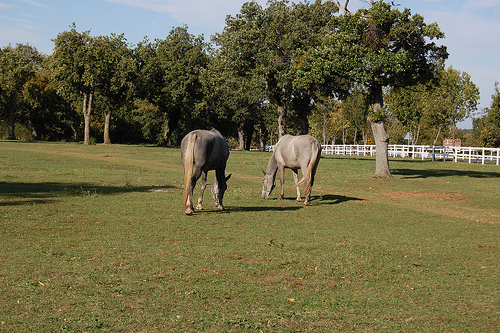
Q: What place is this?
A: It is a field.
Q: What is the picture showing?
A: It is showing a field.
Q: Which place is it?
A: It is a field.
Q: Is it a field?
A: Yes, it is a field.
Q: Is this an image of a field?
A: Yes, it is showing a field.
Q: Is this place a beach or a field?
A: It is a field.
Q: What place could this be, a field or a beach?
A: It is a field.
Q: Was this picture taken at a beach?
A: No, the picture was taken in a field.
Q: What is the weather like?
A: It is cloudy.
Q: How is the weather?
A: It is cloudy.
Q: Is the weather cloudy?
A: Yes, it is cloudy.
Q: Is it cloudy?
A: Yes, it is cloudy.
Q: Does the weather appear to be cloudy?
A: Yes, it is cloudy.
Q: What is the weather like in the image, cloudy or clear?
A: It is cloudy.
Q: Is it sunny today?
A: No, it is cloudy.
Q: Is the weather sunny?
A: No, it is cloudy.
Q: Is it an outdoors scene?
A: Yes, it is outdoors.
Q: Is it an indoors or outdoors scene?
A: It is outdoors.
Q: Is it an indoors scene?
A: No, it is outdoors.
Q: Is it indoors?
A: No, it is outdoors.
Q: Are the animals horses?
A: Yes, all the animals are horses.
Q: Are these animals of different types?
A: No, all the animals are horses.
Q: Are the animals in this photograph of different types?
A: No, all the animals are horses.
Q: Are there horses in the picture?
A: Yes, there is a horse.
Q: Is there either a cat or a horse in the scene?
A: Yes, there is a horse.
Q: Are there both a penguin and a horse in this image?
A: No, there is a horse but no penguins.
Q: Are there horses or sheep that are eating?
A: Yes, the horse is eating.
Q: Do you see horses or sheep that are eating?
A: Yes, the horse is eating.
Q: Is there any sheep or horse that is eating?
A: Yes, the horse is eating.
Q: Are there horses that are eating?
A: Yes, there is a horse that is eating.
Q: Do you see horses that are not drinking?
A: Yes, there is a horse that is eating .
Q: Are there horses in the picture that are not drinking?
A: Yes, there is a horse that is eating.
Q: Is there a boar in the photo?
A: No, there are no boars.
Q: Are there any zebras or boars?
A: No, there are no boars or zebras.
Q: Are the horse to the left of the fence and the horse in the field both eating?
A: Yes, both the horse and the horse are eating.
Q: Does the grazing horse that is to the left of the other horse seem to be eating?
A: Yes, the horse is eating.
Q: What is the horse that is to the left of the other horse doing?
A: The horse is eating.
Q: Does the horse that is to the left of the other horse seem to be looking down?
A: No, the horse is eating.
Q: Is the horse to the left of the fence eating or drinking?
A: The horse is eating.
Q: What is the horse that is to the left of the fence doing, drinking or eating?
A: The horse is eating.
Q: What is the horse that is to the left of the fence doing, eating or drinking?
A: The horse is eating.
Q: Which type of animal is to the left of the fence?
A: The animal is a horse.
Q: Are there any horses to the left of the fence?
A: Yes, there is a horse to the left of the fence.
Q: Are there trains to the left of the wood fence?
A: No, there is a horse to the left of the fence.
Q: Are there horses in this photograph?
A: Yes, there is a horse.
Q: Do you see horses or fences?
A: Yes, there is a horse.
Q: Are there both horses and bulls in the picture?
A: No, there is a horse but no bulls.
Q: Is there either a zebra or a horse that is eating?
A: Yes, the horse is eating.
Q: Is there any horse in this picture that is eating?
A: Yes, there is a horse that is eating.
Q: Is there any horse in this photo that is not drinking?
A: Yes, there is a horse that is eating.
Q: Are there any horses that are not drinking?
A: Yes, there is a horse that is eating.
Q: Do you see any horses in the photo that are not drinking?
A: Yes, there is a horse that is eating .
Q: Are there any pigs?
A: No, there are no pigs.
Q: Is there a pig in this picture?
A: No, there are no pigs.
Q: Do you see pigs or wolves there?
A: No, there are no pigs or wolves.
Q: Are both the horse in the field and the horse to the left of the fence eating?
A: Yes, both the horse and the horse are eating.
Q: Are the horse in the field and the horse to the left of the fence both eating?
A: Yes, both the horse and the horse are eating.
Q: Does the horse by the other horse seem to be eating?
A: Yes, the horse is eating.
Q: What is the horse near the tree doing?
A: The horse is eating.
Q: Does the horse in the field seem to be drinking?
A: No, the horse is eating.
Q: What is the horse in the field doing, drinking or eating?
A: The horse is eating.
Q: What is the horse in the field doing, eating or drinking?
A: The horse is eating.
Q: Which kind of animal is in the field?
A: The animal is a horse.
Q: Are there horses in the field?
A: Yes, there is a horse in the field.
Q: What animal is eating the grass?
A: The horse is eating the grass.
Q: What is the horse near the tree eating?
A: The horse is eating grass.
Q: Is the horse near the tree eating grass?
A: Yes, the horse is eating grass.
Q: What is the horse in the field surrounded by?
A: The horse is surrounded by the fence.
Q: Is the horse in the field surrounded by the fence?
A: Yes, the horse is surrounded by the fence.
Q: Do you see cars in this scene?
A: No, there are no cars.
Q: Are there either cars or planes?
A: No, there are no cars or planes.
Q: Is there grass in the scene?
A: Yes, there is grass.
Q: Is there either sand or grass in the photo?
A: Yes, there is grass.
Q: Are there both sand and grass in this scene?
A: No, there is grass but no sand.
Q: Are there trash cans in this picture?
A: No, there are no trash cans.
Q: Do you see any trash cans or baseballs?
A: No, there are no trash cans or baseballs.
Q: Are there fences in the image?
A: Yes, there is a fence.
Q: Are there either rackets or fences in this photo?
A: Yes, there is a fence.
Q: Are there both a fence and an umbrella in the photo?
A: No, there is a fence but no umbrellas.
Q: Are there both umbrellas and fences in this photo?
A: No, there is a fence but no umbrellas.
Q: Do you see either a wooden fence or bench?
A: Yes, there is a wood fence.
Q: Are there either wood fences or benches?
A: Yes, there is a wood fence.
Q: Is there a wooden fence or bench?
A: Yes, there is a wood fence.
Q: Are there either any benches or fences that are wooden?
A: Yes, the fence is wooden.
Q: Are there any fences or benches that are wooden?
A: Yes, the fence is wooden.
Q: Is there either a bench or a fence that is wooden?
A: Yes, the fence is wooden.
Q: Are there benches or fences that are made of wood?
A: Yes, the fence is made of wood.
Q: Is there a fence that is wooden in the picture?
A: Yes, there is a wood fence.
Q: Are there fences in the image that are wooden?
A: Yes, there is a fence that is wooden.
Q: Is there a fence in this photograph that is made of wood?
A: Yes, there is a fence that is made of wood.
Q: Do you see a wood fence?
A: Yes, there is a fence that is made of wood.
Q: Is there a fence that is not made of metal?
A: Yes, there is a fence that is made of wood.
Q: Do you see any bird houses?
A: No, there are no bird houses.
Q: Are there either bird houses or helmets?
A: No, there are no bird houses or helmets.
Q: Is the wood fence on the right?
A: Yes, the fence is on the right of the image.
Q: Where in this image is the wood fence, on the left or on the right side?
A: The fence is on the right of the image.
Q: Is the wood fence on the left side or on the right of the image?
A: The fence is on the right of the image.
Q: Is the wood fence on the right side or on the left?
A: The fence is on the right of the image.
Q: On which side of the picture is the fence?
A: The fence is on the right of the image.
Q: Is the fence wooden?
A: Yes, the fence is wooden.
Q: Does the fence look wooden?
A: Yes, the fence is wooden.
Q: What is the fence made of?
A: The fence is made of wood.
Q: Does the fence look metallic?
A: No, the fence is wooden.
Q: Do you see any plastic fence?
A: No, there is a fence but it is made of wood.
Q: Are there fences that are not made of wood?
A: No, there is a fence but it is made of wood.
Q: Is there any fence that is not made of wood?
A: No, there is a fence but it is made of wood.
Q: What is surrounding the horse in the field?
A: The fence is surrounding the horse.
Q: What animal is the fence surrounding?
A: The fence is surrounding the horse.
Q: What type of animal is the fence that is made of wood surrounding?
A: The fence is surrounding the horse.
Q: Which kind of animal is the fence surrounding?
A: The fence is surrounding the horse.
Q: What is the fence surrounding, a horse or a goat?
A: The fence is surrounding a horse.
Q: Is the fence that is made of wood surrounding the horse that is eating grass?
A: Yes, the fence is surrounding the horse.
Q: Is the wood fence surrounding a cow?
A: No, the fence is surrounding the horse.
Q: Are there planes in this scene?
A: No, there are no planes.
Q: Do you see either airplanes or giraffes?
A: No, there are no airplanes or giraffes.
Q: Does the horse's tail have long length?
A: Yes, the tail is long.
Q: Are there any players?
A: No, there are no players.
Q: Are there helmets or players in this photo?
A: No, there are no players or helmets.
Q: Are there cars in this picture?
A: No, there are no cars.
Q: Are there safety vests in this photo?
A: No, there are no safety vests.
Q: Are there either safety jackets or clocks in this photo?
A: No, there are no safety jackets or clocks.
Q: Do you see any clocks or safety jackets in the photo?
A: No, there are no safety jackets or clocks.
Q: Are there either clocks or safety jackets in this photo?
A: No, there are no safety jackets or clocks.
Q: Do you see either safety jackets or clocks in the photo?
A: No, there are no safety jackets or clocks.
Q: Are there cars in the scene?
A: No, there are no cars.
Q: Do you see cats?
A: No, there are no cats.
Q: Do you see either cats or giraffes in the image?
A: No, there are no cats or giraffes.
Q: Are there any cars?
A: No, there are no cars.